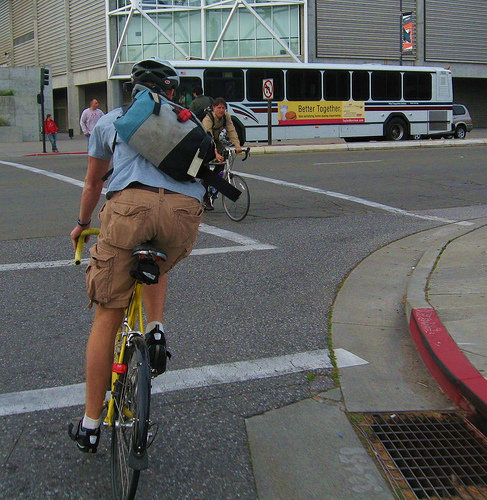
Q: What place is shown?
A: It is a road.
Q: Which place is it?
A: It is a road.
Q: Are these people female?
A: No, they are both male and female.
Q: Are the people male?
A: No, they are both male and female.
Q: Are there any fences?
A: No, there are no fences.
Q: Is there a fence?
A: No, there are no fences.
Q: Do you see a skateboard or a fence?
A: No, there are no fences or skateboards.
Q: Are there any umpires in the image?
A: No, there are no umpires.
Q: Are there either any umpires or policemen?
A: No, there are no umpires or policemen.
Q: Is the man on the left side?
A: Yes, the man is on the left of the image.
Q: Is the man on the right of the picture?
A: No, the man is on the left of the image.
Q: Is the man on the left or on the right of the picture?
A: The man is on the left of the image.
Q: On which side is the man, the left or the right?
A: The man is on the left of the image.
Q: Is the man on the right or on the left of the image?
A: The man is on the left of the image.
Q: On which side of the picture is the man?
A: The man is on the left of the image.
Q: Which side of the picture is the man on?
A: The man is on the left of the image.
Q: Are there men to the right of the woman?
A: Yes, there is a man to the right of the woman.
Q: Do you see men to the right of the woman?
A: Yes, there is a man to the right of the woman.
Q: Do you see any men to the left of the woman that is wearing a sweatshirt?
A: No, the man is to the right of the woman.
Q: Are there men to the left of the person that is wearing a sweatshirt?
A: No, the man is to the right of the woman.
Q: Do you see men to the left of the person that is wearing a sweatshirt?
A: No, the man is to the right of the woman.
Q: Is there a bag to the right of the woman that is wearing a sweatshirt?
A: No, there is a man to the right of the woman.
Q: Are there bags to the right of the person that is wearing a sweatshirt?
A: No, there is a man to the right of the woman.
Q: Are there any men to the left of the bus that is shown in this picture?
A: Yes, there is a man to the left of the bus.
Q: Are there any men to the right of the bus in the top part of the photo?
A: No, the man is to the left of the bus.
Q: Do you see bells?
A: No, there are no bells.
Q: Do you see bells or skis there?
A: No, there are no bells or skis.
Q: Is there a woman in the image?
A: Yes, there is a woman.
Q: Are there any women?
A: Yes, there is a woman.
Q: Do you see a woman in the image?
A: Yes, there is a woman.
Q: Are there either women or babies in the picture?
A: Yes, there is a woman.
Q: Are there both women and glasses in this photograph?
A: No, there is a woman but no glasses.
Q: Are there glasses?
A: No, there are no glasses.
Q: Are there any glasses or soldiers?
A: No, there are no glasses or soldiers.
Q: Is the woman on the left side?
A: Yes, the woman is on the left of the image.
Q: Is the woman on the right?
A: No, the woman is on the left of the image.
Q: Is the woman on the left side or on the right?
A: The woman is on the left of the image.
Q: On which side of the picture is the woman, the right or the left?
A: The woman is on the left of the image.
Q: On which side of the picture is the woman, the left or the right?
A: The woman is on the left of the image.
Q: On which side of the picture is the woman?
A: The woman is on the left of the image.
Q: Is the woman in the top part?
A: Yes, the woman is in the top of the image.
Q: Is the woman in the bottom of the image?
A: No, the woman is in the top of the image.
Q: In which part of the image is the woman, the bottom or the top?
A: The woman is in the top of the image.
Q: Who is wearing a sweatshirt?
A: The woman is wearing a sweatshirt.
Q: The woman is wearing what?
A: The woman is wearing a sweatshirt.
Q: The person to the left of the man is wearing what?
A: The woman is wearing a sweatshirt.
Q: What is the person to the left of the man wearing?
A: The woman is wearing a sweatshirt.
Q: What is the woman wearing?
A: The woman is wearing a sweatshirt.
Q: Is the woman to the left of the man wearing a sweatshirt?
A: Yes, the woman is wearing a sweatshirt.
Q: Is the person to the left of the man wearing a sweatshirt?
A: Yes, the woman is wearing a sweatshirt.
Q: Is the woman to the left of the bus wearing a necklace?
A: No, the woman is wearing a sweatshirt.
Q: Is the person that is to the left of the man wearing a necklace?
A: No, the woman is wearing a sweatshirt.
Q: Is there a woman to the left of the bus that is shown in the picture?
A: Yes, there is a woman to the left of the bus.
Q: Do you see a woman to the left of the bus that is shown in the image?
A: Yes, there is a woman to the left of the bus.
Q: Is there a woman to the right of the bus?
A: No, the woman is to the left of the bus.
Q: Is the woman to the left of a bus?
A: Yes, the woman is to the left of a bus.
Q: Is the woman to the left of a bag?
A: No, the woman is to the left of a bus.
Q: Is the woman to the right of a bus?
A: No, the woman is to the left of a bus.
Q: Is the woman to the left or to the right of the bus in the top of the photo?
A: The woman is to the left of the bus.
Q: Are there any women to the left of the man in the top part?
A: Yes, there is a woman to the left of the man.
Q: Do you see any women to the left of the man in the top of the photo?
A: Yes, there is a woman to the left of the man.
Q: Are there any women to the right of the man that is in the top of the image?
A: No, the woman is to the left of the man.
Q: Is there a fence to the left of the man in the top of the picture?
A: No, there is a woman to the left of the man.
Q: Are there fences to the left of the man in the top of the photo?
A: No, there is a woman to the left of the man.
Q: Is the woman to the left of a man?
A: Yes, the woman is to the left of a man.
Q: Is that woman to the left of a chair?
A: No, the woman is to the left of a man.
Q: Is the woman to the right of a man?
A: No, the woman is to the left of a man.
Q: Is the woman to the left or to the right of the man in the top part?
A: The woman is to the left of the man.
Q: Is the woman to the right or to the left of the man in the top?
A: The woman is to the left of the man.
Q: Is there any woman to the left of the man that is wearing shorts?
A: Yes, there is a woman to the left of the man.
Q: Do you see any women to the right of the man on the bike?
A: No, the woman is to the left of the man.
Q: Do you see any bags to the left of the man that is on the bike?
A: No, there is a woman to the left of the man.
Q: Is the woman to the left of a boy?
A: No, the woman is to the left of a man.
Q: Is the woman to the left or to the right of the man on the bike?
A: The woman is to the left of the man.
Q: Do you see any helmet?
A: Yes, there is a helmet.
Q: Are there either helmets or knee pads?
A: Yes, there is a helmet.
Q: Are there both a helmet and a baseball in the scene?
A: No, there is a helmet but no baseballs.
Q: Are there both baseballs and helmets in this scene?
A: No, there is a helmet but no baseballs.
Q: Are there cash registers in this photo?
A: No, there are no cash registers.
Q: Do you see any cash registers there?
A: No, there are no cash registers.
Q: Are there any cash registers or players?
A: No, there are no cash registers or players.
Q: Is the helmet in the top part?
A: Yes, the helmet is in the top of the image.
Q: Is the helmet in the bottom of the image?
A: No, the helmet is in the top of the image.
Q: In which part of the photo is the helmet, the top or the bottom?
A: The helmet is in the top of the image.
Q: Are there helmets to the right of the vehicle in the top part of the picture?
A: No, the helmet is to the left of the bus.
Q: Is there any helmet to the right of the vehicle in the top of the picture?
A: No, the helmet is to the left of the bus.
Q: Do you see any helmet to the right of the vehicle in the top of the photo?
A: No, the helmet is to the left of the bus.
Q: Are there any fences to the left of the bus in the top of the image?
A: No, there is a helmet to the left of the bus.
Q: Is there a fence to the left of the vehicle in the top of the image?
A: No, there is a helmet to the left of the bus.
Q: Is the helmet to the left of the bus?
A: Yes, the helmet is to the left of the bus.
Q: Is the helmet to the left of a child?
A: No, the helmet is to the left of the bus.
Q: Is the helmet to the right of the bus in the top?
A: No, the helmet is to the left of the bus.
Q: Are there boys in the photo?
A: No, there are no boys.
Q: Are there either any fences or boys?
A: No, there are no boys or fences.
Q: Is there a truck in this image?
A: No, there are no trucks.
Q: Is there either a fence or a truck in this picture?
A: No, there are no trucks or fences.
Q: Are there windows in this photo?
A: Yes, there is a window.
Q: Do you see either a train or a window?
A: Yes, there is a window.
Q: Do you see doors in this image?
A: No, there are no doors.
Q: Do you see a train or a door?
A: No, there are no doors or trains.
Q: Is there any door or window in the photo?
A: Yes, there is a window.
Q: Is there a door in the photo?
A: No, there are no doors.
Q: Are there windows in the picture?
A: Yes, there is a window.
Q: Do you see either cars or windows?
A: Yes, there is a window.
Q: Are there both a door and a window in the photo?
A: No, there is a window but no doors.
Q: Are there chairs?
A: No, there are no chairs.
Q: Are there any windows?
A: Yes, there is a window.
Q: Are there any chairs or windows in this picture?
A: Yes, there is a window.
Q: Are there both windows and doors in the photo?
A: No, there is a window but no doors.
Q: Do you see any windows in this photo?
A: Yes, there is a window.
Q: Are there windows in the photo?
A: Yes, there is a window.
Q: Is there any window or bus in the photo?
A: Yes, there is a window.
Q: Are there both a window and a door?
A: No, there is a window but no doors.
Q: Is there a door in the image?
A: No, there are no doors.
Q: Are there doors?
A: No, there are no doors.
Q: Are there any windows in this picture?
A: Yes, there is a window.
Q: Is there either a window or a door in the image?
A: Yes, there is a window.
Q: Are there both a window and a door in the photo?
A: No, there is a window but no doors.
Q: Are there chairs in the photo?
A: No, there are no chairs.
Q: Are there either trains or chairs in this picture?
A: No, there are no chairs or trains.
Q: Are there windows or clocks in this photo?
A: Yes, there is a window.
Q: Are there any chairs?
A: No, there are no chairs.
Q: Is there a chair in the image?
A: No, there are no chairs.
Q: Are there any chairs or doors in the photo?
A: No, there are no chairs or doors.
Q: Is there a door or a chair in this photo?
A: No, there are no chairs or doors.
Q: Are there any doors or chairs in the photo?
A: No, there are no chairs or doors.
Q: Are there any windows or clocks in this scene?
A: Yes, there is a window.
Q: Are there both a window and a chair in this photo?
A: No, there is a window but no chairs.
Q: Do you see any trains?
A: No, there are no trains.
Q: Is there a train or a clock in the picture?
A: No, there are no trains or clocks.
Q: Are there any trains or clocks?
A: No, there are no trains or clocks.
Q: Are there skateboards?
A: No, there are no skateboards.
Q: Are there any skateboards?
A: No, there are no skateboards.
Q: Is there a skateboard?
A: No, there are no skateboards.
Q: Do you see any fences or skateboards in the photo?
A: No, there are no skateboards or fences.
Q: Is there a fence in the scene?
A: No, there are no fences.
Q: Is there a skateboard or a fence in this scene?
A: No, there are no fences or skateboards.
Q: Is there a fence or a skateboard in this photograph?
A: No, there are no fences or skateboards.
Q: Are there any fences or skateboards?
A: No, there are no fences or skateboards.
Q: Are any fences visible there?
A: No, there are no fences.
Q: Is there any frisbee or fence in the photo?
A: No, there are no fences or frisbees.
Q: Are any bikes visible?
A: Yes, there is a bike.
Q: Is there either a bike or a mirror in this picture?
A: Yes, there is a bike.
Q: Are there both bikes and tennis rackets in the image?
A: No, there is a bike but no rackets.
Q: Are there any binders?
A: No, there are no binders.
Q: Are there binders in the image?
A: No, there are no binders.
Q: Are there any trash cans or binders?
A: No, there are no binders or trash cans.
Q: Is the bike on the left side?
A: Yes, the bike is on the left of the image.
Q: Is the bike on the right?
A: No, the bike is on the left of the image.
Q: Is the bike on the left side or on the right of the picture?
A: The bike is on the left of the image.